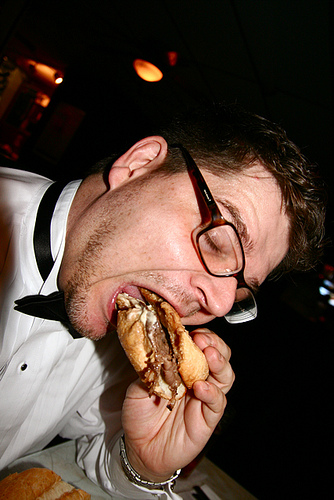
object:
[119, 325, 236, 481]
hand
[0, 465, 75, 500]
bread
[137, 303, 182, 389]
meat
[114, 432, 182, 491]
band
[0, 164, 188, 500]
shirt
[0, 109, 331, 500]
man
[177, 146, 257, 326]
glasses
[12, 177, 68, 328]
necktie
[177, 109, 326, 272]
hair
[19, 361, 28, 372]
button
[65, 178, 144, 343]
beard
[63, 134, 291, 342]
face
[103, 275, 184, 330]
mouth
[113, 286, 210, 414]
bread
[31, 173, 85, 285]
band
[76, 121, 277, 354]
man's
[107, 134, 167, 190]
ear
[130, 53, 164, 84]
lights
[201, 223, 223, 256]
eyes